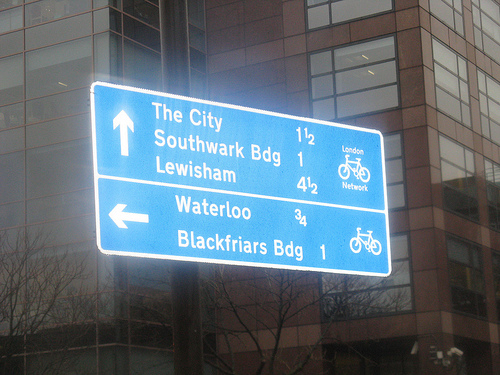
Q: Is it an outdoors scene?
A: Yes, it is outdoors.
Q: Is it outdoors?
A: Yes, it is outdoors.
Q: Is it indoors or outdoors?
A: It is outdoors.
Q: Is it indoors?
A: No, it is outdoors.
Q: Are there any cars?
A: No, there are no cars.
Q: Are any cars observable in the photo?
A: No, there are no cars.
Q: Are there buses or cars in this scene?
A: No, there are no cars or buses.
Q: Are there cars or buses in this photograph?
A: No, there are no cars or buses.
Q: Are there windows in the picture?
A: Yes, there are windows.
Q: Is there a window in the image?
A: Yes, there are windows.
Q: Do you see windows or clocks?
A: Yes, there are windows.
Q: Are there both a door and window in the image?
A: No, there are windows but no doors.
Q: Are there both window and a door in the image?
A: No, there are windows but no doors.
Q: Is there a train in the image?
A: No, there are no trains.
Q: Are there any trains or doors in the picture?
A: No, there are no trains or doors.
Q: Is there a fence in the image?
A: No, there are no fences.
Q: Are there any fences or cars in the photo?
A: No, there are no fences or cars.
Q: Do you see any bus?
A: No, there are no buses.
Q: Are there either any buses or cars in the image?
A: No, there are no buses or cars.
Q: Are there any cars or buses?
A: No, there are no buses or cars.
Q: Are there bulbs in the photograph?
A: No, there are no bulbs.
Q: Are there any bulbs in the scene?
A: No, there are no bulbs.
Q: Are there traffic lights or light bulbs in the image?
A: No, there are no light bulbs or traffic lights.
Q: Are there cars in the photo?
A: No, there are no cars.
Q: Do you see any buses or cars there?
A: No, there are no cars or buses.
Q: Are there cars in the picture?
A: No, there are no cars.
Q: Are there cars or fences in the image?
A: No, there are no cars or fences.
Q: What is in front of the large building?
A: The tree is in front of the building.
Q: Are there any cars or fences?
A: No, there are no cars or fences.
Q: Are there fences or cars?
A: No, there are no cars or fences.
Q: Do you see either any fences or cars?
A: No, there are no cars or fences.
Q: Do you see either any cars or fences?
A: No, there are no cars or fences.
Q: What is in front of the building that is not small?
A: The tree is in front of the building.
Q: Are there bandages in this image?
A: No, there are no bandages.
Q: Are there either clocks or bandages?
A: No, there are no bandages or clocks.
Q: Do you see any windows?
A: Yes, there is a window.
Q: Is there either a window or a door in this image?
A: Yes, there is a window.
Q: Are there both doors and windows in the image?
A: No, there is a window but no doors.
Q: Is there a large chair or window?
A: Yes, there is a large window.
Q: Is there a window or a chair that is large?
A: Yes, the window is large.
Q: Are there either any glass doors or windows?
A: Yes, there is a glass window.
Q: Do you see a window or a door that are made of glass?
A: Yes, the window is made of glass.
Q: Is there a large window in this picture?
A: Yes, there is a large window.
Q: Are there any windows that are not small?
A: Yes, there is a large window.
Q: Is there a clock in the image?
A: No, there are no clocks.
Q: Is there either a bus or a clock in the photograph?
A: No, there are no clocks or buses.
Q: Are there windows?
A: Yes, there is a window.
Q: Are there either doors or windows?
A: Yes, there is a window.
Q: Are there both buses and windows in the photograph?
A: No, there is a window but no buses.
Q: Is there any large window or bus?
A: Yes, there is a large window.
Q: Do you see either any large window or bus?
A: Yes, there is a large window.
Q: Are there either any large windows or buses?
A: Yes, there is a large window.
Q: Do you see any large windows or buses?
A: Yes, there is a large window.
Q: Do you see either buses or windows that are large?
A: Yes, the window is large.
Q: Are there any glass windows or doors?
A: Yes, there is a glass window.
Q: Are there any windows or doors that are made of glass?
A: Yes, the window is made of glass.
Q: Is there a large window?
A: Yes, there is a large window.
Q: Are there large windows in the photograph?
A: Yes, there is a large window.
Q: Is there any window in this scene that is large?
A: Yes, there is a window that is large.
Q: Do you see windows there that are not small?
A: Yes, there is a large window.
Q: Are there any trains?
A: No, there are no trains.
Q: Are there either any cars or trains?
A: No, there are no trains or cars.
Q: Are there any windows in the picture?
A: Yes, there is a window.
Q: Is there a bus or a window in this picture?
A: Yes, there is a window.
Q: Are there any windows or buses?
A: Yes, there is a window.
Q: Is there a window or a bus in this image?
A: Yes, there is a window.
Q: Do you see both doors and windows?
A: No, there is a window but no doors.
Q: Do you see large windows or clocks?
A: Yes, there is a large window.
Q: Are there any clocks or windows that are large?
A: Yes, the window is large.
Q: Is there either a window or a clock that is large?
A: Yes, the window is large.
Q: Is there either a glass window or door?
A: Yes, there is a glass window.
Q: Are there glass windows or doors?
A: Yes, there is a glass window.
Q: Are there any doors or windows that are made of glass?
A: Yes, the window is made of glass.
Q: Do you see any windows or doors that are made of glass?
A: Yes, the window is made of glass.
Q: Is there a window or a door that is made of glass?
A: Yes, the window is made of glass.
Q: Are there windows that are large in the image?
A: Yes, there is a large window.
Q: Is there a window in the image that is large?
A: Yes, there is a window that is large.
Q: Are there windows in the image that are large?
A: Yes, there is a window that is large.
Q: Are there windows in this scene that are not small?
A: Yes, there is a large window.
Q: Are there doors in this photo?
A: No, there are no doors.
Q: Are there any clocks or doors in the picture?
A: No, there are no doors or clocks.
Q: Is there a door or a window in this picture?
A: Yes, there is a window.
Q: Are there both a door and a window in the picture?
A: No, there is a window but no doors.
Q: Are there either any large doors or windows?
A: Yes, there is a large window.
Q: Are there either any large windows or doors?
A: Yes, there is a large window.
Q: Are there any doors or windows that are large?
A: Yes, the window is large.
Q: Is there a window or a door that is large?
A: Yes, the window is large.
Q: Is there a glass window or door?
A: Yes, there is a glass window.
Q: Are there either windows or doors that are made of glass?
A: Yes, the window is made of glass.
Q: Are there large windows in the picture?
A: Yes, there is a large window.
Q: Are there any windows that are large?
A: Yes, there is a window that is large.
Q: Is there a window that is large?
A: Yes, there is a window that is large.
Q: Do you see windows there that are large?
A: Yes, there is a window that is large.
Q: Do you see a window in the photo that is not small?
A: Yes, there is a large window.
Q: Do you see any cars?
A: No, there are no cars.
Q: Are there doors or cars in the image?
A: No, there are no cars or doors.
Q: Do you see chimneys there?
A: No, there are no chimneys.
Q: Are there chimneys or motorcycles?
A: No, there are no chimneys or motorcycles.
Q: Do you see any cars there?
A: No, there are no cars.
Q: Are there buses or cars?
A: No, there are no cars or buses.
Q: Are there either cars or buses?
A: No, there are no cars or buses.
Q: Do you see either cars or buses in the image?
A: No, there are no cars or buses.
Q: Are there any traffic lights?
A: No, there are no traffic lights.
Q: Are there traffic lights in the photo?
A: No, there are no traffic lights.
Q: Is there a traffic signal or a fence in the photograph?
A: No, there are no traffic lights or fences.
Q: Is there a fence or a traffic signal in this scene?
A: No, there are no traffic lights or fences.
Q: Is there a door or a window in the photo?
A: Yes, there is a window.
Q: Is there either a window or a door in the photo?
A: Yes, there is a window.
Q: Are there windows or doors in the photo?
A: Yes, there is a window.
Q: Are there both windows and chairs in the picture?
A: No, there is a window but no chairs.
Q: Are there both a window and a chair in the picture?
A: No, there is a window but no chairs.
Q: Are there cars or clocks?
A: No, there are no cars or clocks.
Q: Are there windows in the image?
A: Yes, there are windows.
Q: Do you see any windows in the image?
A: Yes, there are windows.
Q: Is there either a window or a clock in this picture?
A: Yes, there are windows.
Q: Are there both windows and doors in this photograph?
A: No, there are windows but no doors.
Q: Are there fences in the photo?
A: No, there are no fences.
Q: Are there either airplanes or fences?
A: No, there are no fences or airplanes.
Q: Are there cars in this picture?
A: No, there are no cars.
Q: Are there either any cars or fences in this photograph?
A: No, there are no cars or fences.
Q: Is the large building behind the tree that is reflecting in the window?
A: Yes, the building is behind the tree.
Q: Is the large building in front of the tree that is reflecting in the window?
A: No, the building is behind the tree.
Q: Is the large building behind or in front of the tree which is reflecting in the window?
A: The building is behind the tree.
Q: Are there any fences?
A: No, there are no fences.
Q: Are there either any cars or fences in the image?
A: No, there are no fences or cars.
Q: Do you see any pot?
A: No, there are no pots.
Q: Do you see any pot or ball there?
A: No, there are no pots or balls.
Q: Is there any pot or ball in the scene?
A: No, there are no pots or balls.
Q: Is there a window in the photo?
A: Yes, there are windows.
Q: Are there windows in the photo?
A: Yes, there are windows.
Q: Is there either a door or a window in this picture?
A: Yes, there are windows.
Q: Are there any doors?
A: No, there are no doors.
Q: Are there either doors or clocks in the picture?
A: No, there are no doors or clocks.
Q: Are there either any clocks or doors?
A: No, there are no doors or clocks.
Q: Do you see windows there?
A: Yes, there are windows.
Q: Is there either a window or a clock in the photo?
A: Yes, there are windows.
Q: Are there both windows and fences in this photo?
A: No, there are windows but no fences.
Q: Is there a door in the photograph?
A: No, there are no doors.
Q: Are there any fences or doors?
A: No, there are no doors or fences.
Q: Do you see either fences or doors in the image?
A: No, there are no doors or fences.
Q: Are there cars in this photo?
A: No, there are no cars.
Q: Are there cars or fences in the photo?
A: No, there are no cars or fences.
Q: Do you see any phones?
A: No, there are no phones.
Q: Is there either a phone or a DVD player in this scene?
A: No, there are no phones or DVD players.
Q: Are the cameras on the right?
A: Yes, the cameras are on the right of the image.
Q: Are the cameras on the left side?
A: No, the cameras are on the right of the image.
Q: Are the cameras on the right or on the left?
A: The cameras are on the right of the image.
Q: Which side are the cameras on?
A: The cameras are on the right of the image.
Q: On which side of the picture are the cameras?
A: The cameras are on the right of the image.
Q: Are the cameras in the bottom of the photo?
A: Yes, the cameras are in the bottom of the image.